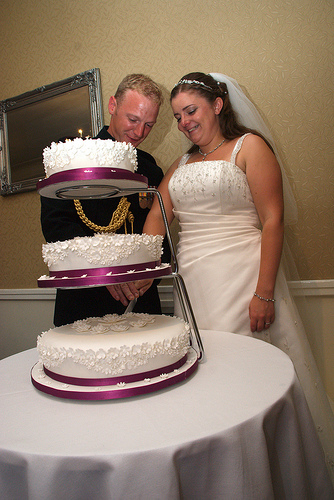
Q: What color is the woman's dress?
A: White.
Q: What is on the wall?
A: Mirror.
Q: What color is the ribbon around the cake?
A: Purple.